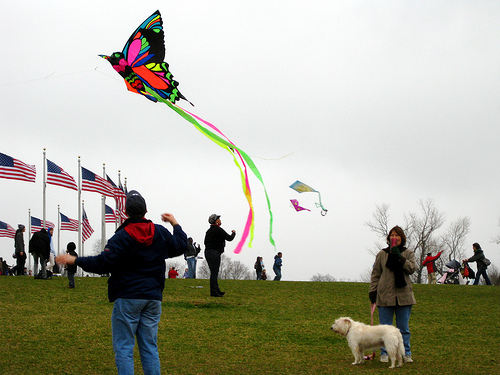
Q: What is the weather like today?
A: It is cloudy.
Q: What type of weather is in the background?
A: It is cloudy.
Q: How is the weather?
A: It is cloudy.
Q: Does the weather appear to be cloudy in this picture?
A: Yes, it is cloudy.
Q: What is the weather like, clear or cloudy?
A: It is cloudy.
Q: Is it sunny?
A: No, it is cloudy.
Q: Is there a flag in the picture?
A: Yes, there is a flag.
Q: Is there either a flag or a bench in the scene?
A: Yes, there is a flag.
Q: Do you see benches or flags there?
A: Yes, there is a flag.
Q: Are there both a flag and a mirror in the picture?
A: No, there is a flag but no mirrors.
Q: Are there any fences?
A: No, there are no fences.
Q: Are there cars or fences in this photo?
A: No, there are no fences or cars.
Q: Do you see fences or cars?
A: No, there are no fences or cars.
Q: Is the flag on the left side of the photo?
A: Yes, the flag is on the left of the image.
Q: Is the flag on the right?
A: No, the flag is on the left of the image.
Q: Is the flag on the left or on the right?
A: The flag is on the left of the image.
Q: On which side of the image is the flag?
A: The flag is on the left of the image.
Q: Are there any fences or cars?
A: No, there are no fences or cars.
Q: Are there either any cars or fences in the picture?
A: No, there are no fences or cars.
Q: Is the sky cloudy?
A: Yes, the sky is cloudy.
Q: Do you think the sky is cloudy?
A: Yes, the sky is cloudy.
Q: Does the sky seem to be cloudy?
A: Yes, the sky is cloudy.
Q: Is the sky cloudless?
A: No, the sky is cloudy.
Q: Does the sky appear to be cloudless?
A: No, the sky is cloudy.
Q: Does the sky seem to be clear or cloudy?
A: The sky is cloudy.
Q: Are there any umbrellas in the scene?
A: No, there are no umbrellas.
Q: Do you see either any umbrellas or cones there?
A: No, there are no umbrellas or cones.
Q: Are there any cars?
A: No, there are no cars.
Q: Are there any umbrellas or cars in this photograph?
A: No, there are no cars or umbrellas.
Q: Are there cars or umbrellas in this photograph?
A: No, there are no cars or umbrellas.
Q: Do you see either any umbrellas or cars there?
A: No, there are no cars or umbrellas.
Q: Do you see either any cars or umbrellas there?
A: No, there are no cars or umbrellas.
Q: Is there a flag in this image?
A: Yes, there is a flag.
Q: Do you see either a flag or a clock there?
A: Yes, there is a flag.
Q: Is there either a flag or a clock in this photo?
A: Yes, there is a flag.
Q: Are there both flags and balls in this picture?
A: No, there is a flag but no balls.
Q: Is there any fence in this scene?
A: No, there are no fences.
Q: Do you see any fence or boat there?
A: No, there are no fences or boats.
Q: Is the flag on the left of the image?
A: Yes, the flag is on the left of the image.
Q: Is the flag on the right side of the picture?
A: No, the flag is on the left of the image.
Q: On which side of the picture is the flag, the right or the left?
A: The flag is on the left of the image.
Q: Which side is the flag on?
A: The flag is on the left of the image.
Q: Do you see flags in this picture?
A: Yes, there is a flag.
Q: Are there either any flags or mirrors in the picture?
A: Yes, there is a flag.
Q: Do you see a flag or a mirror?
A: Yes, there is a flag.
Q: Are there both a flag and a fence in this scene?
A: No, there is a flag but no fences.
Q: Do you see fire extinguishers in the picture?
A: No, there are no fire extinguishers.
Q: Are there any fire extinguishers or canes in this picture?
A: No, there are no fire extinguishers or canes.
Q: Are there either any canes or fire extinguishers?
A: No, there are no fire extinguishers or canes.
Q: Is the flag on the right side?
A: No, the flag is on the left of the image.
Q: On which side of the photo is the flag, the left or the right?
A: The flag is on the left of the image.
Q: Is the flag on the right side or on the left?
A: The flag is on the left of the image.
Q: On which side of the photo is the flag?
A: The flag is on the left of the image.